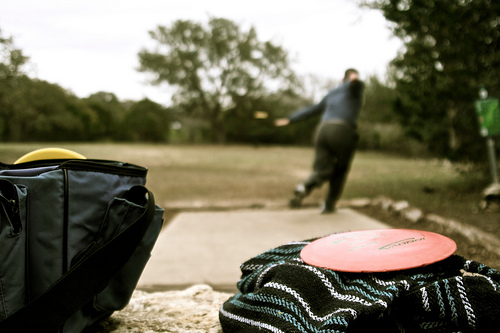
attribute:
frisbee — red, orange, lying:
[298, 219, 460, 276]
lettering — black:
[373, 230, 432, 252]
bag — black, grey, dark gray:
[0, 157, 164, 332]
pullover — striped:
[212, 231, 495, 330]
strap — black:
[2, 182, 168, 332]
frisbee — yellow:
[5, 143, 93, 165]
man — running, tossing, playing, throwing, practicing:
[269, 66, 368, 216]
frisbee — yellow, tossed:
[253, 108, 272, 122]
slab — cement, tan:
[137, 206, 396, 294]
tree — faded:
[126, 11, 306, 155]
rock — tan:
[112, 283, 236, 332]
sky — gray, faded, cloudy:
[9, 1, 401, 109]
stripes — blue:
[228, 282, 347, 332]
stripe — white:
[213, 304, 292, 332]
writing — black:
[366, 235, 435, 257]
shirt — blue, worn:
[290, 79, 369, 126]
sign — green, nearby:
[474, 97, 499, 145]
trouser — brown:
[289, 120, 359, 216]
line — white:
[168, 185, 498, 259]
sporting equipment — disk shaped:
[12, 138, 462, 286]